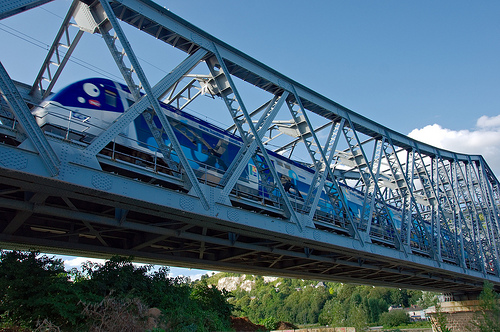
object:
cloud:
[473, 116, 499, 135]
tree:
[261, 286, 281, 328]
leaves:
[212, 291, 220, 295]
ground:
[364, 327, 425, 332]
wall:
[455, 311, 500, 331]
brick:
[458, 321, 463, 323]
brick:
[454, 319, 458, 321]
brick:
[460, 319, 463, 322]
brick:
[452, 319, 454, 321]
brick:
[466, 316, 468, 318]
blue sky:
[0, 3, 499, 142]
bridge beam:
[239, 55, 331, 111]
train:
[30, 75, 485, 268]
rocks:
[222, 280, 229, 284]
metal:
[76, 166, 101, 182]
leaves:
[37, 298, 46, 302]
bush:
[160, 301, 226, 332]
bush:
[378, 310, 411, 327]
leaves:
[14, 253, 19, 263]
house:
[404, 291, 426, 321]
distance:
[165, 269, 242, 292]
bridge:
[0, 0, 499, 293]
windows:
[104, 89, 116, 108]